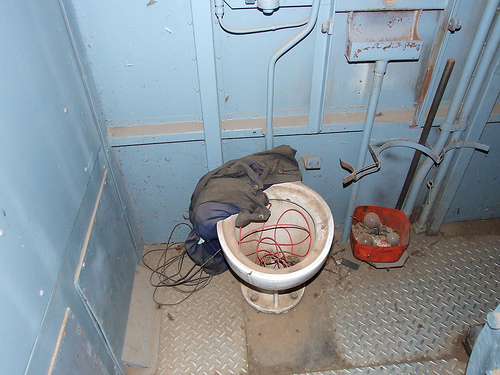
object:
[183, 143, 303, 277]
clothing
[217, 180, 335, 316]
toilet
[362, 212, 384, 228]
light bulb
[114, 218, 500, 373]
floor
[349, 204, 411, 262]
container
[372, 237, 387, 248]
junk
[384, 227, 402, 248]
bulb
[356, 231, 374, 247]
bulb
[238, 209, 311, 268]
wires